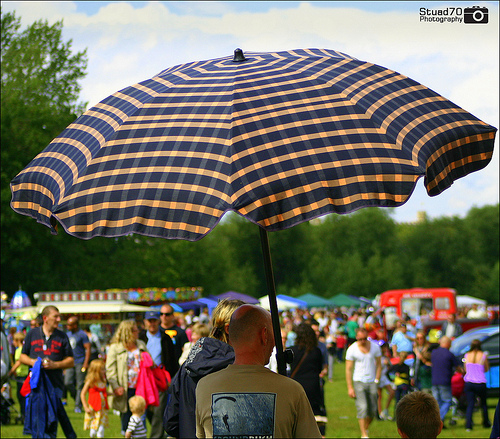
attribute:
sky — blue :
[75, 1, 399, 21]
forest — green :
[0, 204, 492, 294]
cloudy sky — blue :
[0, 2, 498, 217]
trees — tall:
[0, 11, 499, 300]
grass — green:
[327, 379, 353, 437]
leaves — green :
[303, 218, 399, 286]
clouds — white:
[82, 1, 185, 48]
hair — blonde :
[112, 311, 129, 336]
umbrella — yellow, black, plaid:
[14, 41, 494, 243]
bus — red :
[356, 274, 467, 336]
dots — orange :
[287, 132, 352, 177]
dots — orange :
[168, 148, 283, 172]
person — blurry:
[341, 327, 381, 437]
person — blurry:
[385, 318, 413, 360]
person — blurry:
[431, 332, 459, 421]